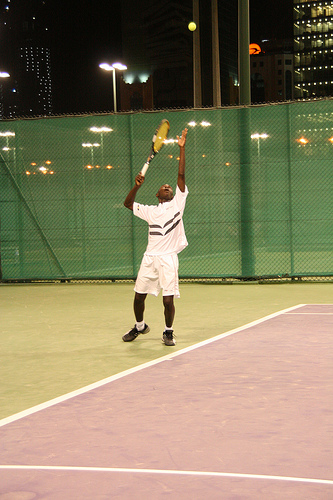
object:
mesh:
[48, 147, 85, 211]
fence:
[0, 94, 331, 286]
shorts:
[133, 251, 181, 298]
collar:
[157, 201, 170, 208]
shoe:
[122, 322, 150, 342]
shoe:
[162, 328, 176, 346]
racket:
[138, 118, 170, 178]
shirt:
[131, 184, 189, 252]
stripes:
[148, 224, 163, 230]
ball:
[187, 21, 197, 32]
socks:
[135, 319, 145, 333]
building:
[289, 0, 332, 159]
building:
[249, 49, 293, 101]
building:
[0, 0, 58, 114]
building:
[119, 13, 240, 106]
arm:
[176, 146, 186, 206]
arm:
[122, 186, 149, 221]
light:
[98, 62, 114, 72]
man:
[120, 122, 188, 346]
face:
[158, 183, 174, 198]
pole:
[111, 70, 118, 111]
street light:
[111, 61, 127, 73]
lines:
[1, 302, 301, 428]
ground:
[1, 282, 332, 498]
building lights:
[324, 33, 328, 38]